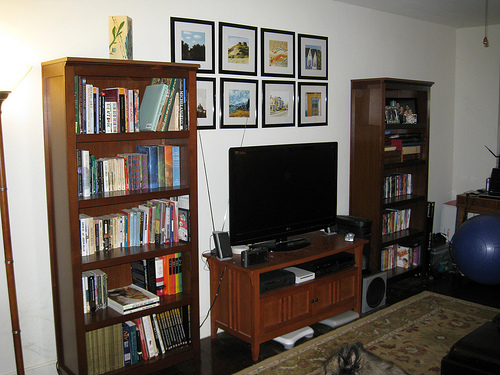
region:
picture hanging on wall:
[218, 74, 258, 124]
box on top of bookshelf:
[100, 15, 142, 60]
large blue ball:
[437, 210, 499, 292]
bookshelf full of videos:
[347, 74, 432, 311]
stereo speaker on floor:
[362, 271, 389, 311]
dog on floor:
[318, 333, 405, 373]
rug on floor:
[272, 290, 497, 373]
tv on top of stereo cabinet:
[197, 135, 348, 265]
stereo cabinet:
[208, 245, 382, 356]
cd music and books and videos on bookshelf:
[72, 247, 201, 312]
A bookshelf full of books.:
[40, 55, 220, 370]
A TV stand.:
[205, 230, 380, 355]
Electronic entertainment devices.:
[255, 240, 355, 295]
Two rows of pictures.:
[160, 0, 340, 135]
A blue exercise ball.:
[435, 205, 495, 300]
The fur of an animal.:
[295, 325, 415, 370]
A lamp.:
[0, 40, 45, 365]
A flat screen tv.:
[220, 130, 350, 255]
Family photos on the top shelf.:
[365, 75, 435, 130]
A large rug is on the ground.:
[255, 281, 492, 371]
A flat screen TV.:
[220, 130, 360, 250]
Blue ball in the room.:
[440, 205, 495, 280]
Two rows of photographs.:
[165, 10, 365, 130]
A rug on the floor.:
[235, 281, 495, 371]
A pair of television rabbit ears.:
[185, 95, 257, 260]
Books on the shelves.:
[57, 75, 207, 365]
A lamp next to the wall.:
[0, 86, 65, 371]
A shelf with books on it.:
[383, 207, 429, 242]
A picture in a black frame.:
[215, 75, 260, 131]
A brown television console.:
[202, 217, 379, 358]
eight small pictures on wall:
[169, 12, 333, 129]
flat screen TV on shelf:
[223, 144, 338, 249]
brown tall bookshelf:
[33, 53, 198, 373]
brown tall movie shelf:
[345, 71, 427, 287]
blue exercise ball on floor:
[443, 196, 498, 288]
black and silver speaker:
[212, 229, 233, 263]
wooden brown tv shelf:
[203, 227, 371, 346]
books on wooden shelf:
[69, 73, 188, 311]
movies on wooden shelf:
[378, 165, 414, 240]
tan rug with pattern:
[244, 291, 498, 373]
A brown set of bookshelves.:
[26, 47, 216, 373]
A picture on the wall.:
[210, 15, 255, 75]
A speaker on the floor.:
[350, 260, 395, 311]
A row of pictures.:
[195, 70, 335, 125]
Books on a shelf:
[75, 135, 190, 200]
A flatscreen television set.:
[215, 121, 361, 247]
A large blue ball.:
[426, 203, 497, 293]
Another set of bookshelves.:
[335, 70, 456, 305]